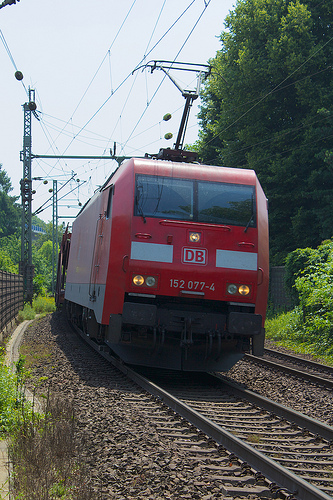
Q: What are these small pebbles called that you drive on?
A: Gravel.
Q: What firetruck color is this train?
A: Red.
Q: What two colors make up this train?
A: Red and white.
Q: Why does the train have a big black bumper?
A: So it takes no damage.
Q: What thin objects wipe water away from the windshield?
A: Wipers.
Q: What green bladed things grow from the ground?
A: Grass.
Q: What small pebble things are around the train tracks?
A: Gravel.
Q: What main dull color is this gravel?
A: Grey.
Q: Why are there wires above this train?
A: It's electric.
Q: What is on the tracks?
A: Train.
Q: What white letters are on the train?
A: 152 077 - 4.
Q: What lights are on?
A: Headlights.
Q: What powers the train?
A: Electricity.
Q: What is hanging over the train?
A: Power cables.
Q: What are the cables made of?
A: Metal.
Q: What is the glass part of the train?
A: Windshield.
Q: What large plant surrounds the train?
A: Trees.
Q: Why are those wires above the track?
A: To give the train power.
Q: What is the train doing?
A: Moving along the tracks.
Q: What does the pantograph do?
A: Conducts electricity.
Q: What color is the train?
A: Red.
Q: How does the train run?
A: By electricity.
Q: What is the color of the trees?
A: Green.